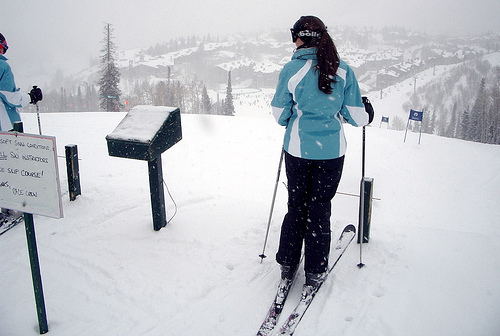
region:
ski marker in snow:
[403, 105, 428, 147]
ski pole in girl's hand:
[354, 99, 371, 271]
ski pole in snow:
[251, 115, 285, 271]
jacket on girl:
[283, 60, 352, 157]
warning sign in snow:
[0, 125, 67, 330]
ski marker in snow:
[380, 111, 388, 126]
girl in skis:
[245, 14, 369, 334]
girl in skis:
[241, 222, 361, 334]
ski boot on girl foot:
[299, 258, 327, 287]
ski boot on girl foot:
[271, 248, 297, 276]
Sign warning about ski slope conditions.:
[0, 130, 70, 217]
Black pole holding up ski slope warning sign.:
[21, 212, 47, 332]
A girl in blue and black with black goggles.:
[256, 15, 375, 334]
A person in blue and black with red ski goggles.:
[1, 34, 32, 221]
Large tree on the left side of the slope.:
[99, 20, 122, 110]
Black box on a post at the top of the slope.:
[105, 103, 183, 234]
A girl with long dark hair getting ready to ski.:
[270, 15, 372, 284]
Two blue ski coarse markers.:
[378, 108, 423, 142]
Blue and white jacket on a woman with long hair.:
[270, 49, 368, 159]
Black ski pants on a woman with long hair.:
[276, 147, 346, 280]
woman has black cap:
[287, 30, 352, 84]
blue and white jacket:
[265, 59, 366, 157]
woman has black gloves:
[352, 91, 380, 106]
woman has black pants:
[265, 151, 348, 281]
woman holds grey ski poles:
[257, 99, 391, 286]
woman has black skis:
[262, 220, 362, 334]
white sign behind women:
[1, 151, 103, 233]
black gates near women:
[62, 141, 81, 204]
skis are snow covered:
[247, 223, 366, 334]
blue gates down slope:
[390, 88, 432, 148]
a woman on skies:
[180, 18, 472, 333]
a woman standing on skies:
[226, 82, 424, 332]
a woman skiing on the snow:
[243, 28, 419, 331]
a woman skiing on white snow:
[154, 22, 477, 304]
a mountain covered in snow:
[162, 16, 467, 320]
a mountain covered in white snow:
[128, 28, 494, 255]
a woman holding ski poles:
[222, 13, 397, 201]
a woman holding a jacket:
[242, 29, 432, 234]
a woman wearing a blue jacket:
[233, 23, 370, 199]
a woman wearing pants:
[254, 34, 472, 334]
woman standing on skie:
[126, 0, 451, 335]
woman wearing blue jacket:
[267, 39, 375, 166]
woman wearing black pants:
[264, 124, 356, 286]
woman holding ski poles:
[232, 70, 386, 275]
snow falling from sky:
[14, 4, 461, 303]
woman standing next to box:
[70, 3, 437, 325]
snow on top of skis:
[207, 185, 377, 332]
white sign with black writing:
[0, 120, 96, 328]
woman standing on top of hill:
[3, 5, 495, 334]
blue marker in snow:
[370, 71, 449, 162]